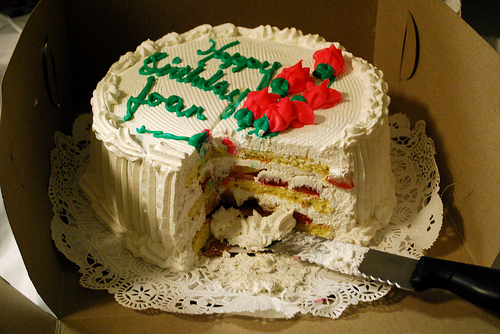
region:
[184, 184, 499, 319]
a black handled knife with frosting on it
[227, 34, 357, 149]
sugar frosting roses on a cake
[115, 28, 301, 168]
the words "happy birthday Joan" written in green frosting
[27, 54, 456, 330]
a white doily underneath the cake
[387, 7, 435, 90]
a slit and fold of cardboard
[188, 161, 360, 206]
one layer of red colored filling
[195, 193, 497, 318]
a serrated knife in a cake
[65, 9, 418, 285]
a birthday cake with three layers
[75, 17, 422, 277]
a birthday cake with a slice taken out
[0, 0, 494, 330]
a cake inside of a cardboard box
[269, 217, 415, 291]
a metal knife blade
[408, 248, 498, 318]
a black knife handle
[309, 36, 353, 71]
a pink flower made of frosting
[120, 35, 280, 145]
green writing on the cake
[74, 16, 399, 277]
a white frosted cake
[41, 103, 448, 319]
a white doily under the cake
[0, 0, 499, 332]
a brown cardboard box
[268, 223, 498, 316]
a knife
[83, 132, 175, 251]
ridged sides of the cake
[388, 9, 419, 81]
the handle of a box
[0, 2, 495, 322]
Birthday cake in a box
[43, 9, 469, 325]
Birthday cake for Joan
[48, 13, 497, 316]
Birthday cake with a knife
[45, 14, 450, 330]
Strawberry birthday cake with frosting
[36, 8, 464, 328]
Orange, green, and white birthday cake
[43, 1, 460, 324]
Cake with three layers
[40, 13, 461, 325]
Cake with slice missing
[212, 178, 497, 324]
Knife with cake frosting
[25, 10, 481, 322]
Cut birthday cake for Joan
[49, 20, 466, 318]
Cake with white icing for Joan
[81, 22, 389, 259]
white frosting on cake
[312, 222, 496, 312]
knife with black handle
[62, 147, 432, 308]
white paper underneath cake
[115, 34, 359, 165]
green writing on cake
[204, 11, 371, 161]
red flowers on cake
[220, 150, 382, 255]
cake layered in yellow and white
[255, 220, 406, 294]
blade of knife with cake on it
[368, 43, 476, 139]
brown cardboard box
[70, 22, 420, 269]
frosting on cake is white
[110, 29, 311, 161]
cake is for birthday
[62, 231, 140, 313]
a portion of doily with a cake on it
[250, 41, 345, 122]
five red frosting roses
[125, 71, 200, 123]
"Joan" in green frosting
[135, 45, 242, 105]
"Birthday" in green frosting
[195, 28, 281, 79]
"Happy" in green frosting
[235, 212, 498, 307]
a knife with frosting on it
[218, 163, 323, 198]
red fruit filling in a cake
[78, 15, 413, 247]
a birthday cake for Joan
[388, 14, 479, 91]
a portion of cardboard box used to hold a cake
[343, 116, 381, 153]
white frosting on a birthday cake